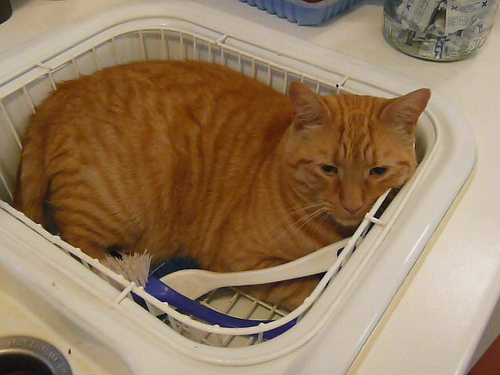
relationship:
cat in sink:
[11, 58, 435, 314] [2, 1, 482, 373]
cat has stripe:
[11, 58, 435, 314] [367, 95, 382, 165]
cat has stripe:
[11, 58, 435, 314] [333, 93, 347, 160]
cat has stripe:
[11, 58, 435, 314] [277, 164, 331, 245]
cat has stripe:
[11, 58, 435, 314] [68, 117, 144, 231]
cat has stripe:
[11, 58, 435, 314] [56, 214, 111, 242]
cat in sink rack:
[11, 58, 435, 314] [2, 6, 446, 349]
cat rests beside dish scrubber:
[11, 58, 435, 314] [136, 232, 359, 319]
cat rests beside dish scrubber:
[11, 58, 435, 314] [85, 250, 300, 343]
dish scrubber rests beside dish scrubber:
[136, 232, 359, 319] [85, 250, 300, 343]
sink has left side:
[2, 1, 482, 373] [0, 250, 140, 374]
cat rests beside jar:
[11, 58, 435, 314] [379, 2, 497, 66]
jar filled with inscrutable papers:
[379, 2, 497, 66] [385, 0, 492, 62]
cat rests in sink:
[11, 58, 435, 314] [2, 1, 482, 373]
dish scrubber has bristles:
[136, 232, 359, 319] [134, 251, 201, 309]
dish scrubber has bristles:
[85, 250, 300, 343] [88, 247, 168, 297]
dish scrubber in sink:
[136, 232, 359, 319] [2, 1, 482, 373]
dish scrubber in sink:
[85, 250, 300, 343] [2, 1, 482, 373]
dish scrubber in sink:
[143, 237, 356, 317] [2, 1, 482, 373]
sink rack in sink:
[2, 6, 446, 349] [2, 1, 482, 373]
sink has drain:
[2, 1, 482, 373] [0, 329, 77, 373]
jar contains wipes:
[379, 2, 497, 66] [385, 0, 492, 62]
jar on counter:
[379, 2, 497, 66] [1, 0, 499, 374]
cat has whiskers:
[11, 58, 435, 314] [259, 196, 337, 253]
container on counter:
[225, 0, 365, 30] [1, 0, 499, 374]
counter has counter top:
[1, 0, 499, 374] [1, 0, 499, 373]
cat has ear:
[11, 58, 435, 314] [376, 77, 433, 136]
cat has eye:
[11, 58, 435, 314] [363, 159, 394, 182]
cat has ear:
[11, 58, 435, 314] [285, 77, 333, 136]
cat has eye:
[11, 58, 435, 314] [317, 160, 340, 178]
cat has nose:
[11, 58, 435, 314] [340, 203, 365, 215]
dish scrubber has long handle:
[136, 232, 359, 319] [207, 231, 367, 292]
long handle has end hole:
[207, 231, 367, 292] [332, 245, 364, 265]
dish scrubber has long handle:
[85, 250, 300, 343] [157, 277, 301, 342]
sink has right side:
[2, 1, 482, 373] [0, 1, 478, 374]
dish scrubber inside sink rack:
[136, 232, 359, 319] [2, 6, 446, 349]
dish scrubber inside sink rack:
[85, 250, 300, 343] [2, 6, 446, 349]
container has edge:
[232, 0, 364, 25] [280, 1, 333, 28]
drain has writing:
[0, 329, 77, 373] [6, 335, 69, 373]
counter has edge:
[1, 0, 499, 374] [451, 277, 499, 374]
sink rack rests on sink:
[2, 6, 446, 349] [2, 1, 482, 373]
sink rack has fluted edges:
[2, 6, 446, 349] [2, 9, 442, 345]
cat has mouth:
[11, 58, 435, 314] [331, 213, 367, 222]